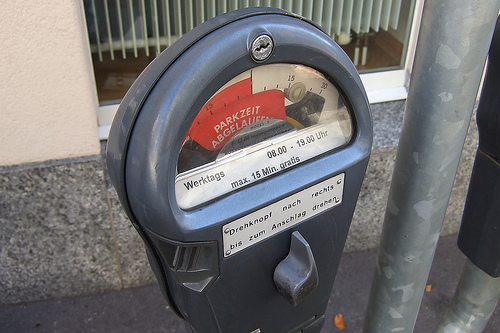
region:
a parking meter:
[111, 4, 427, 329]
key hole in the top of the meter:
[247, 30, 277, 62]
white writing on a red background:
[198, 91, 296, 152]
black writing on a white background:
[223, 175, 349, 260]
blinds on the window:
[91, 3, 421, 93]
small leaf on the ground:
[333, 310, 351, 328]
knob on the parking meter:
[271, 229, 320, 306]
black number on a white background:
[283, 71, 298, 83]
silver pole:
[357, 0, 490, 330]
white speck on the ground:
[160, 300, 171, 312]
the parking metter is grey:
[151, 33, 376, 331]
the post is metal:
[391, 108, 453, 331]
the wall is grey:
[43, 202, 109, 285]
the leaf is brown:
[333, 311, 350, 330]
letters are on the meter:
[233, 178, 340, 243]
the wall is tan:
[3, 15, 95, 167]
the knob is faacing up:
[276, 226, 323, 301]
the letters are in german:
[193, 89, 329, 199]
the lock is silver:
[253, 37, 276, 60]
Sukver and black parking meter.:
[280, 305, 325, 312]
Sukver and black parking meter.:
[243, 239, 333, 243]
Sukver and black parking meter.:
[143, 202, 175, 216]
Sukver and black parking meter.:
[50, 234, 370, 255]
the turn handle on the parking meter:
[273, 230, 317, 307]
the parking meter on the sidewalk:
[105, 5, 372, 330]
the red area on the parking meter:
[180, 78, 287, 150]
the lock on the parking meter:
[251, 35, 273, 60]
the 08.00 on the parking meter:
[267, 145, 287, 158]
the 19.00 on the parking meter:
[296, 135, 314, 146]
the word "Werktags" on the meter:
[183, 170, 225, 188]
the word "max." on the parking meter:
[231, 178, 250, 190]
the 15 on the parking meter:
[287, 73, 294, 80]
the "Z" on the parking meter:
[238, 108, 245, 118]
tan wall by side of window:
[2, 2, 419, 167]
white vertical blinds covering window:
[81, 0, 406, 105]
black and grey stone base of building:
[0, 100, 480, 301]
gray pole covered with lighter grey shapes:
[365, 0, 490, 325]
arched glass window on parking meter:
[130, 15, 360, 215]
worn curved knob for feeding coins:
[271, 220, 316, 310]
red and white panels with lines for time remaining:
[185, 60, 340, 155]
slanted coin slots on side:
[140, 225, 220, 277]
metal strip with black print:
[220, 171, 345, 256]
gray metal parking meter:
[88, 12, 367, 330]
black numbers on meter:
[264, 145, 289, 158]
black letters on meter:
[315, 130, 331, 142]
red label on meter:
[192, 89, 289, 144]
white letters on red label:
[211, 112, 278, 144]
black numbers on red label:
[202, 100, 214, 111]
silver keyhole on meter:
[250, 34, 275, 64]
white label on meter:
[252, 67, 341, 111]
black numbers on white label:
[282, 74, 296, 81]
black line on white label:
[315, 87, 323, 96]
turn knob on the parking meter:
[267, 225, 324, 306]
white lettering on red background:
[207, 101, 267, 148]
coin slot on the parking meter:
[165, 240, 202, 271]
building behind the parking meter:
[3, 5, 469, 279]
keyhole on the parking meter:
[248, 32, 278, 62]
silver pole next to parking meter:
[350, 5, 489, 328]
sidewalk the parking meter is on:
[9, 235, 496, 332]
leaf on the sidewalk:
[324, 310, 351, 330]